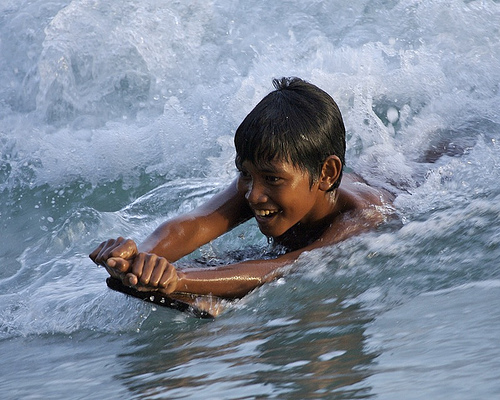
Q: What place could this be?
A: It is an ocean.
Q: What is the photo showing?
A: It is showing an ocean.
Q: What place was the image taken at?
A: It was taken at the ocean.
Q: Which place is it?
A: It is an ocean.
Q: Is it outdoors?
A: Yes, it is outdoors.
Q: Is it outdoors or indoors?
A: It is outdoors.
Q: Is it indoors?
A: No, it is outdoors.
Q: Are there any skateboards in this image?
A: No, there are no skateboards.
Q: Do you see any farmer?
A: No, there are no farmers.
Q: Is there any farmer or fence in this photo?
A: No, there are no farmers or fences.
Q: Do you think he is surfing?
A: Yes, the boy is surfing.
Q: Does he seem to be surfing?
A: Yes, the boy is surfing.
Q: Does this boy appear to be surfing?
A: Yes, the boy is surfing.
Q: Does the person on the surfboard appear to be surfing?
A: Yes, the boy is surfing.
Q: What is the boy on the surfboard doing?
A: The boy is surfing.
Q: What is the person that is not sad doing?
A: The boy is surfing.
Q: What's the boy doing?
A: The boy is surfing.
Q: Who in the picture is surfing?
A: The boy is surfing.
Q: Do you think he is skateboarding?
A: No, the boy is surfing.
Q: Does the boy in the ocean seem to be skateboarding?
A: No, the boy is surfing.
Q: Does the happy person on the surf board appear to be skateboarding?
A: No, the boy is surfing.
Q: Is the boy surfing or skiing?
A: The boy is surfing.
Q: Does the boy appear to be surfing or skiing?
A: The boy is surfing.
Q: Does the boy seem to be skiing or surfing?
A: The boy is surfing.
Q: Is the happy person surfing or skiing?
A: The boy is surfing.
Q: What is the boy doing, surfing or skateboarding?
A: The boy is surfing.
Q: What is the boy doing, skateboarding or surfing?
A: The boy is surfing.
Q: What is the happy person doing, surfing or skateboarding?
A: The boy is surfing.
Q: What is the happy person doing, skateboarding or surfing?
A: The boy is surfing.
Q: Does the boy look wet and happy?
A: Yes, the boy is wet and happy.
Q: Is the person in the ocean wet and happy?
A: Yes, the boy is wet and happy.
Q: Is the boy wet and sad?
A: No, the boy is wet but happy.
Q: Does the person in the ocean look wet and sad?
A: No, the boy is wet but happy.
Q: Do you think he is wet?
A: Yes, the boy is wet.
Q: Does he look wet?
A: Yes, the boy is wet.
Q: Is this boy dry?
A: No, the boy is wet.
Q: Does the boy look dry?
A: No, the boy is wet.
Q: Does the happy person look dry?
A: No, the boy is wet.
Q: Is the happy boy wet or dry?
A: The boy is wet.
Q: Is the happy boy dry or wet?
A: The boy is wet.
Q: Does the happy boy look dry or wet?
A: The boy is wet.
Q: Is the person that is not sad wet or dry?
A: The boy is wet.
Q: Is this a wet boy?
A: Yes, this is a wet boy.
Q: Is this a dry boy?
A: No, this is a wet boy.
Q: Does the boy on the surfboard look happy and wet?
A: Yes, the boy is happy and wet.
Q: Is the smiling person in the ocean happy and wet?
A: Yes, the boy is happy and wet.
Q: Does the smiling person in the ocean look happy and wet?
A: Yes, the boy is happy and wet.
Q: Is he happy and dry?
A: No, the boy is happy but wet.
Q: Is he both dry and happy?
A: No, the boy is happy but wet.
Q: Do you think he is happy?
A: Yes, the boy is happy.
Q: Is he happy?
A: Yes, the boy is happy.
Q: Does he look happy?
A: Yes, the boy is happy.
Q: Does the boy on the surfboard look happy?
A: Yes, the boy is happy.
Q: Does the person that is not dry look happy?
A: Yes, the boy is happy.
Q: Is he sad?
A: No, the boy is happy.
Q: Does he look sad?
A: No, the boy is happy.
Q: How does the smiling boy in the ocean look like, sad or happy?
A: The boy is happy.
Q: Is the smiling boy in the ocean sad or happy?
A: The boy is happy.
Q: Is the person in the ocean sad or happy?
A: The boy is happy.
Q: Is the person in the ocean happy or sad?
A: The boy is happy.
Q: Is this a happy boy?
A: Yes, this is a happy boy.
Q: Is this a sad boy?
A: No, this is a happy boy.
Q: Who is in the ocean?
A: The boy is in the ocean.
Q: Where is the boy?
A: The boy is in the ocean.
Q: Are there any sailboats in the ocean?
A: No, there is a boy in the ocean.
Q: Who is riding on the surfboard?
A: The boy is riding on the surfboard.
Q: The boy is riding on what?
A: The boy is riding on the surf board.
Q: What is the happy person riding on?
A: The boy is riding on the surf board.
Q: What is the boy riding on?
A: The boy is riding on the surf board.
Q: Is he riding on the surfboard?
A: Yes, the boy is riding on the surfboard.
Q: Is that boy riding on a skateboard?
A: No, the boy is riding on the surfboard.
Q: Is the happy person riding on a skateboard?
A: No, the boy is riding on the surfboard.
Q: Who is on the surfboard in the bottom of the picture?
A: The boy is on the surfboard.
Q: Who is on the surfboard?
A: The boy is on the surfboard.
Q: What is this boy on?
A: The boy is on the surf board.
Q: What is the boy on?
A: The boy is on the surf board.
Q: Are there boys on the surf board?
A: Yes, there is a boy on the surf board.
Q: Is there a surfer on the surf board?
A: No, there is a boy on the surf board.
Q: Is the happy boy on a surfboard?
A: Yes, the boy is on a surfboard.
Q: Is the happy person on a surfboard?
A: Yes, the boy is on a surfboard.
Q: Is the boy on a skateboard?
A: No, the boy is on a surfboard.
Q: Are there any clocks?
A: No, there are no clocks.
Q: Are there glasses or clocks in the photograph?
A: No, there are no clocks or glasses.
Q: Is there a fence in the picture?
A: No, there are no fences.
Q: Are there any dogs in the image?
A: No, there are no dogs.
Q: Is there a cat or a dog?
A: No, there are no dogs or cats.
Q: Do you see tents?
A: No, there are no tents.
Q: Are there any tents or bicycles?
A: No, there are no tents or bicycles.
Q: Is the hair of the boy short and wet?
A: Yes, the hair is short and wet.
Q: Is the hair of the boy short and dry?
A: No, the hair is short but wet.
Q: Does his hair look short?
A: Yes, the hair is short.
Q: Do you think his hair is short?
A: Yes, the hair is short.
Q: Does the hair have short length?
A: Yes, the hair is short.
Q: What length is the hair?
A: The hair is short.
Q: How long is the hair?
A: The hair is short.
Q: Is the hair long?
A: No, the hair is short.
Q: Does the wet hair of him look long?
A: No, the hair is short.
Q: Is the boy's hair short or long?
A: The hair is short.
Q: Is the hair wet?
A: Yes, the hair is wet.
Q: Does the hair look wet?
A: Yes, the hair is wet.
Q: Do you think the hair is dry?
A: No, the hair is wet.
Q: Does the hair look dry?
A: No, the hair is wet.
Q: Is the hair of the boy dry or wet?
A: The hair is wet.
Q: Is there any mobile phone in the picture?
A: No, there are no cell phones.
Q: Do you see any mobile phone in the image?
A: No, there are no cell phones.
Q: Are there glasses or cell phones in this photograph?
A: No, there are no cell phones or glasses.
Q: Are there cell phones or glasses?
A: No, there are no cell phones or glasses.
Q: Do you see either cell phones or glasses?
A: No, there are no cell phones or glasses.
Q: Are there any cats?
A: No, there are no cats.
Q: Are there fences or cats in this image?
A: No, there are no cats or fences.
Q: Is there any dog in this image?
A: No, there are no dogs.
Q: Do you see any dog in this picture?
A: No, there are no dogs.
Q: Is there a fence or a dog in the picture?
A: No, there are no dogs or fences.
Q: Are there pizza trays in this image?
A: No, there are no pizza trays.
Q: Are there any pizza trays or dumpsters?
A: No, there are no pizza trays or dumpsters.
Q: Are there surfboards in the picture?
A: Yes, there is a surfboard.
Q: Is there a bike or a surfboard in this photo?
A: Yes, there is a surfboard.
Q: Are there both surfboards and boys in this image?
A: Yes, there are both a surfboard and a boy.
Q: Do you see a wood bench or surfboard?
A: Yes, there is a wood surfboard.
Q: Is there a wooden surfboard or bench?
A: Yes, there is a wood surfboard.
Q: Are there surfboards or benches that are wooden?
A: Yes, the surfboard is wooden.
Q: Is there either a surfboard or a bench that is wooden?
A: Yes, the surfboard is wooden.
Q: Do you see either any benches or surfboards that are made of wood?
A: Yes, the surfboard is made of wood.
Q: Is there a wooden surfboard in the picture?
A: Yes, there is a wood surfboard.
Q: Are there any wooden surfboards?
A: Yes, there is a wood surfboard.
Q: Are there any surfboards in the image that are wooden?
A: Yes, there is a surfboard that is wooden.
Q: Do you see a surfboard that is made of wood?
A: Yes, there is a surfboard that is made of wood.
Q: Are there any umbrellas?
A: No, there are no umbrellas.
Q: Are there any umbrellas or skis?
A: No, there are no umbrellas or skis.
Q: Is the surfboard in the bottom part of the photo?
A: Yes, the surfboard is in the bottom of the image.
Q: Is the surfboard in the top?
A: No, the surfboard is in the bottom of the image.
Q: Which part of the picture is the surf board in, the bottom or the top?
A: The surf board is in the bottom of the image.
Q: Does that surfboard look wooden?
A: Yes, the surfboard is wooden.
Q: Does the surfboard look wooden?
A: Yes, the surfboard is wooden.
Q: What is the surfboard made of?
A: The surfboard is made of wood.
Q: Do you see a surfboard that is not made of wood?
A: No, there is a surfboard but it is made of wood.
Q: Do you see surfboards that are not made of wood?
A: No, there is a surfboard but it is made of wood.